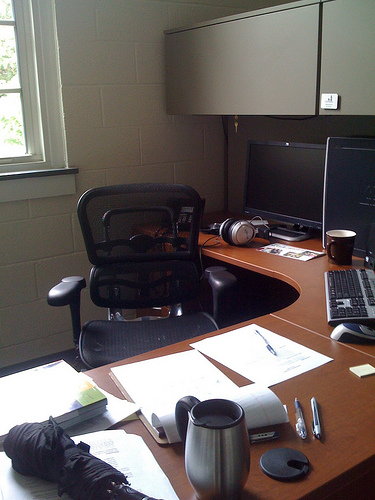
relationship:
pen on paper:
[255, 328, 277, 355] [191, 321, 335, 388]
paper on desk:
[191, 321, 335, 388] [1, 212, 374, 498]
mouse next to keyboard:
[330, 322, 374, 343] [325, 267, 374, 325]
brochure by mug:
[260, 241, 325, 263] [324, 228, 358, 266]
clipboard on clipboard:
[109, 369, 240, 443] [109, 369, 278, 445]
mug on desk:
[177, 397, 249, 499] [1, 212, 374, 498]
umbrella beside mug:
[4, 418, 155, 500] [177, 397, 249, 499]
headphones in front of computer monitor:
[220, 214, 269, 246] [243, 137, 325, 233]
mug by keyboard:
[324, 228, 358, 266] [325, 267, 374, 325]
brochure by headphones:
[260, 241, 325, 263] [220, 214, 269, 246]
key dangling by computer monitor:
[235, 120, 239, 131] [243, 137, 325, 233]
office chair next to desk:
[47, 184, 239, 365] [1, 212, 374, 498]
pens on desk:
[295, 395, 323, 440] [1, 212, 374, 498]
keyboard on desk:
[325, 267, 374, 325] [1, 212, 374, 498]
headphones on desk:
[220, 214, 269, 246] [1, 212, 374, 498]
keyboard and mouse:
[325, 267, 374, 325] [330, 322, 374, 343]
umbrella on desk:
[4, 418, 155, 500] [1, 212, 374, 498]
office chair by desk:
[47, 184, 239, 365] [1, 212, 374, 498]